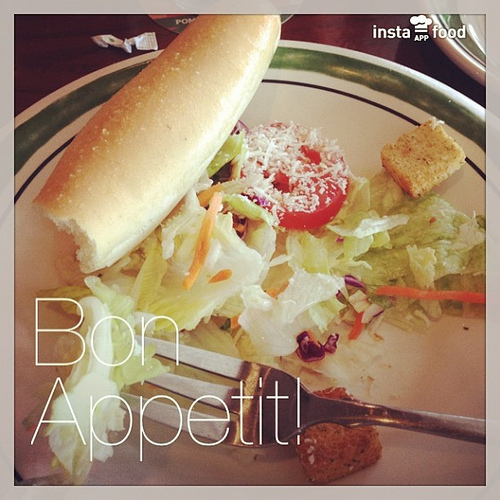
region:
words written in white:
[27, 291, 307, 453]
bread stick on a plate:
[33, 13, 283, 280]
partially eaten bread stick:
[31, 13, 284, 282]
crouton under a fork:
[279, 380, 384, 484]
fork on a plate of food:
[87, 328, 496, 464]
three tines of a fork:
[103, 326, 305, 452]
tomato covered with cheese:
[236, 118, 351, 230]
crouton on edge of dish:
[380, 110, 468, 198]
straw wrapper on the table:
[91, 28, 163, 57]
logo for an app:
[368, 11, 469, 45]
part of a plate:
[464, 325, 479, 332]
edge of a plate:
[386, 409, 396, 441]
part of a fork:
[248, 315, 270, 360]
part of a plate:
[392, 358, 407, 372]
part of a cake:
[338, 441, 345, 447]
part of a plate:
[403, 373, 416, 375]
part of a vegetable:
[304, 334, 306, 346]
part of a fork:
[251, 380, 253, 388]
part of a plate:
[351, 367, 363, 378]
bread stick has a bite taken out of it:
[17, 7, 311, 265]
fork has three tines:
[70, 308, 475, 459]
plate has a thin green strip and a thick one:
[14, 43, 491, 294]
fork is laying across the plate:
[35, 292, 490, 492]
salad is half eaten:
[35, 66, 476, 456]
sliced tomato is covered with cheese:
[230, 110, 360, 235]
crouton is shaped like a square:
[376, 110, 492, 215]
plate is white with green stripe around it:
[13, 48, 490, 495]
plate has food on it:
[15, 52, 492, 488]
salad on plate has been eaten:
[20, 60, 498, 480]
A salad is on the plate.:
[247, 118, 464, 345]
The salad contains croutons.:
[377, 117, 466, 198]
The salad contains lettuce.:
[349, 207, 449, 269]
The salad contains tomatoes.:
[278, 119, 348, 231]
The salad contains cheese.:
[250, 135, 284, 162]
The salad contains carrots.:
[376, 285, 478, 303]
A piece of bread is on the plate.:
[34, 14, 281, 271]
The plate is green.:
[286, 52, 329, 70]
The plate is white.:
[338, 106, 375, 143]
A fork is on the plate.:
[167, 345, 485, 445]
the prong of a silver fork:
[132, 335, 246, 382]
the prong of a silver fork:
[142, 368, 244, 410]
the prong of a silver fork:
[116, 393, 241, 446]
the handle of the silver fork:
[312, 389, 491, 449]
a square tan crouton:
[297, 388, 382, 478]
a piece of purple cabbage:
[296, 329, 338, 361]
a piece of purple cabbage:
[341, 273, 365, 294]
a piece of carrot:
[369, 281, 486, 309]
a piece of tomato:
[240, 120, 346, 227]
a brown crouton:
[382, 115, 461, 197]